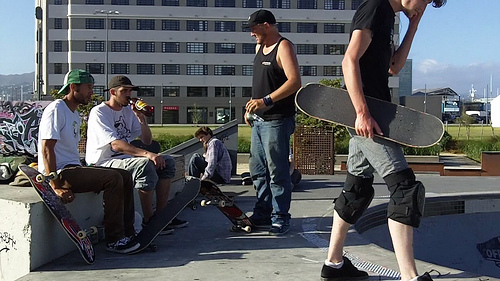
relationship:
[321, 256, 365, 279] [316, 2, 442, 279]
shoe of a man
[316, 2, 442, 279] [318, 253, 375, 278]
man has foot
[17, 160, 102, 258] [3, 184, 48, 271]
skateboard against wall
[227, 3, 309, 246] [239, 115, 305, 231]
man has blue jeans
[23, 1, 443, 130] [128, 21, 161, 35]
building has window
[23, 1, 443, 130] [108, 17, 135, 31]
building has window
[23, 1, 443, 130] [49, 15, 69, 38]
building has window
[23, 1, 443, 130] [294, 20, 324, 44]
building has window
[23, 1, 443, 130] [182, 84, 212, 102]
building has window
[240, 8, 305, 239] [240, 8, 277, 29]
man has black cap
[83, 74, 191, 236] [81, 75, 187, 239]
boy drinking beverage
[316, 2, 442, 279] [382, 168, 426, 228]
man wearing knee pads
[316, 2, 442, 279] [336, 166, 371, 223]
man wearing kneepad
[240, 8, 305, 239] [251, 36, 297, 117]
man wearing vest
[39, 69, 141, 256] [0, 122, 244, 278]
boy in wall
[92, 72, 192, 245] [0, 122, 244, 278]
boy in wall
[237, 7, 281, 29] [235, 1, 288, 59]
black cap on man's head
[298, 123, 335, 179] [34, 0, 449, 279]
waste bin behind boys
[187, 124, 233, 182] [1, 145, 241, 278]
boy sitting on stairs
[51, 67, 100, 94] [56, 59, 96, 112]
hat on boy's head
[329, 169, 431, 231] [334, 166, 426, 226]
knee pads are on boy's knees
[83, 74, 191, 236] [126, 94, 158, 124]
boy drinking from bottle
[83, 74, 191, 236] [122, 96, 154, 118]
boy drinking from bottle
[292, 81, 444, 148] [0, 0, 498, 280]
skateboard in photo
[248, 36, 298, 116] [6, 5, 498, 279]
vest in photo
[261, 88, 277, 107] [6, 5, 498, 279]
wrist band in photo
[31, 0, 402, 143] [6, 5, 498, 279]
building in photo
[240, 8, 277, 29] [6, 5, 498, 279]
black cap in photo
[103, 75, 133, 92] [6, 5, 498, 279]
hat in photo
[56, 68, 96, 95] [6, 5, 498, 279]
hat in photo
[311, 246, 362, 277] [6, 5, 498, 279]
shoes in photo